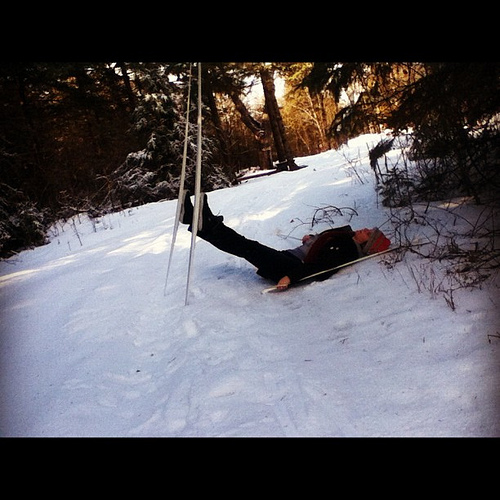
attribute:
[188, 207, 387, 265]
woman — laying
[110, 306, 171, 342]
snow — white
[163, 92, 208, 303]
skis — white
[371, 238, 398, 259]
hat — red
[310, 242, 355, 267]
jacket — black, dark, gray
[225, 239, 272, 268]
pants — black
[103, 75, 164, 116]
branches — covered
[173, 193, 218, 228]
boots — black